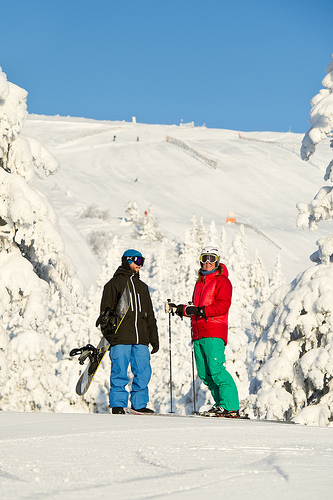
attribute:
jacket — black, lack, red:
[92, 272, 242, 346]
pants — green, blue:
[102, 329, 238, 409]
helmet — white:
[198, 247, 222, 255]